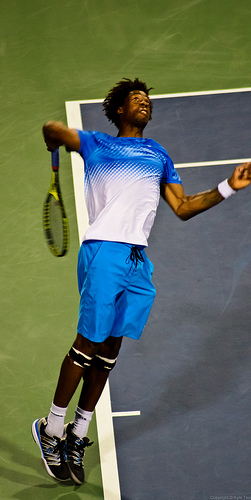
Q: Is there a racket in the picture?
A: Yes, there is a racket.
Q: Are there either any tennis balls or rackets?
A: Yes, there is a racket.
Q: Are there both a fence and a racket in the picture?
A: No, there is a racket but no fences.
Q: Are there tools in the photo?
A: No, there are no tools.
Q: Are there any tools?
A: No, there are no tools.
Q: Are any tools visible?
A: No, there are no tools.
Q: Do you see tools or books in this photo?
A: No, there are no tools or books.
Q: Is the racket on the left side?
A: Yes, the racket is on the left of the image.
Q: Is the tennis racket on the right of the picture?
A: No, the tennis racket is on the left of the image.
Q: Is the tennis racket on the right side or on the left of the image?
A: The tennis racket is on the left of the image.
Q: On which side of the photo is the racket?
A: The racket is on the left of the image.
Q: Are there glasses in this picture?
A: No, there are no glasses.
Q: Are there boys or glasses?
A: No, there are no glasses or boys.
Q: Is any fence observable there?
A: No, there are no fences.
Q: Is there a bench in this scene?
A: No, there are no benches.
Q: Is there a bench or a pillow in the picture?
A: No, there are no benches or pillows.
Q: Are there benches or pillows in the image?
A: No, there are no benches or pillows.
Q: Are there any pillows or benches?
A: No, there are no benches or pillows.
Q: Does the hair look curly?
A: Yes, the hair is curly.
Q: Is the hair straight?
A: No, the hair is curly.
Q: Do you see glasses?
A: No, there are no glasses.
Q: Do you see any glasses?
A: No, there are no glasses.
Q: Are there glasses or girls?
A: No, there are no glasses or girls.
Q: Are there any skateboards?
A: No, there are no skateboards.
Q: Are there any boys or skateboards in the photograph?
A: No, there are no skateboards or boys.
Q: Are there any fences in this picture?
A: No, there are no fences.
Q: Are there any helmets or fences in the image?
A: No, there are no fences or helmets.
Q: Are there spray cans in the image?
A: No, there are no spray cans.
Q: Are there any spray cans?
A: No, there are no spray cans.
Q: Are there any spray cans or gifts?
A: No, there are no spray cans or gifts.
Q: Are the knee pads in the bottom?
A: Yes, the knee pads are in the bottom of the image.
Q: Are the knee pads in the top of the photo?
A: No, the knee pads are in the bottom of the image.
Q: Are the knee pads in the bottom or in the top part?
A: The knee pads are in the bottom of the image.